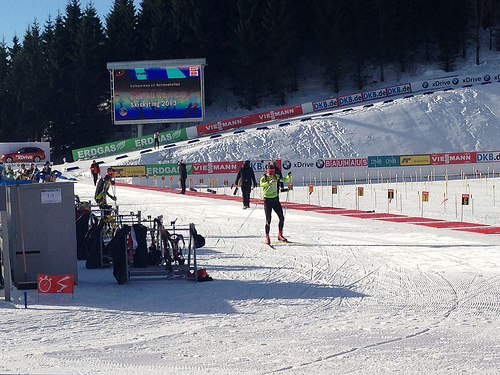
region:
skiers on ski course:
[74, 132, 464, 302]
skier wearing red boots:
[216, 147, 336, 283]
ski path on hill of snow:
[75, 50, 498, 159]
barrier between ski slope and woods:
[116, 69, 492, 134]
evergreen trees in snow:
[38, 12, 295, 170]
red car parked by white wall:
[2, 130, 79, 172]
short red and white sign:
[8, 270, 93, 342]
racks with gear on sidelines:
[82, 139, 334, 287]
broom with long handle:
[5, 180, 57, 313]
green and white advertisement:
[57, 131, 142, 163]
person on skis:
[244, 159, 309, 255]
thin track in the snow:
[264, 266, 469, 373]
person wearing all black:
[222, 151, 261, 219]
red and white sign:
[32, 273, 81, 296]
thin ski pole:
[225, 183, 282, 231]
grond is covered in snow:
[8, 85, 498, 372]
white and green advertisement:
[71, 139, 133, 160]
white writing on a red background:
[192, 160, 242, 172]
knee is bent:
[277, 207, 290, 224]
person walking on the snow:
[221, 154, 261, 214]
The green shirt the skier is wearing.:
[261, 173, 289, 201]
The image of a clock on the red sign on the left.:
[37, 274, 53, 293]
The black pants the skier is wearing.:
[263, 199, 285, 233]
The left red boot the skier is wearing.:
[267, 233, 268, 243]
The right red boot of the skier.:
[277, 231, 286, 243]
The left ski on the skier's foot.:
[267, 239, 276, 251]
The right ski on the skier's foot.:
[280, 235, 305, 252]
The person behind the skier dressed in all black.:
[230, 158, 260, 206]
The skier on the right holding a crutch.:
[105, 175, 120, 206]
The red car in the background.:
[4, 143, 46, 167]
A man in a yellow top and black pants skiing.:
[256, 163, 294, 243]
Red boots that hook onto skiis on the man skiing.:
[263, 231, 287, 246]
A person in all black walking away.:
[231, 159, 256, 209]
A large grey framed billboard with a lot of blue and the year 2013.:
[106, 61, 205, 126]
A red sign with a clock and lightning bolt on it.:
[36, 270, 74, 303]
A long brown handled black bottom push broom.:
[13, 182, 37, 292]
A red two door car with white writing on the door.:
[1, 145, 44, 164]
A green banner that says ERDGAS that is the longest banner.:
[72, 125, 186, 162]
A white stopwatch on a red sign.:
[37, 274, 52, 293]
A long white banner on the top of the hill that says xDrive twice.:
[409, 69, 499, 96]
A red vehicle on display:
[2, 144, 47, 164]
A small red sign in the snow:
[34, 272, 77, 302]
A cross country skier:
[234, 164, 298, 251]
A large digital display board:
[105, 57, 207, 127]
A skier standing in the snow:
[91, 167, 122, 218]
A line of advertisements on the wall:
[111, 149, 498, 186]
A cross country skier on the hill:
[152, 129, 162, 148]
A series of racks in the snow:
[74, 199, 215, 289]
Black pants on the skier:
[262, 193, 287, 236]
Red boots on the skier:
[263, 231, 289, 243]